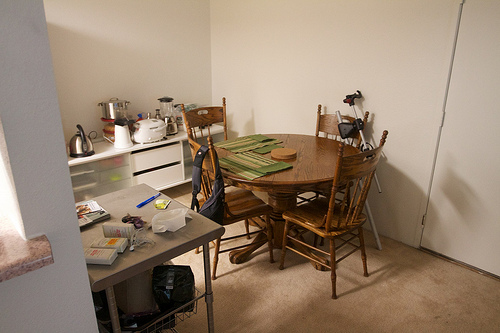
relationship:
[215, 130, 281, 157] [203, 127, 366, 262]
placemat on table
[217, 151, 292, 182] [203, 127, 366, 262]
books on table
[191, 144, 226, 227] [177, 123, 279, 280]
bag on chair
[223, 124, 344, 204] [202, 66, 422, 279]
books on table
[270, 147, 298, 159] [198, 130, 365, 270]
table decoration on table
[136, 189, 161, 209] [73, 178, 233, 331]
blue utencil on table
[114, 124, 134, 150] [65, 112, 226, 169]
box on counter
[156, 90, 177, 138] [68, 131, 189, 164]
metal blender on counter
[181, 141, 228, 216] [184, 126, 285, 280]
bag on chair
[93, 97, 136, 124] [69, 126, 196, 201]
pan on cabinet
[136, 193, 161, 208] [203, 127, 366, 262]
blue utencil on table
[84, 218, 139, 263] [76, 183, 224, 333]
containers on counter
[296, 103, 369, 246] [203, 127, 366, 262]
chair around table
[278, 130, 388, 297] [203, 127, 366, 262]
chair around table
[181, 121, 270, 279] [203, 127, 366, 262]
chair around table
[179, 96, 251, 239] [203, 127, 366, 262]
chair around table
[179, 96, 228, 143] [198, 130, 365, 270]
chair around table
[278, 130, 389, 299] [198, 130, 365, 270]
chair around table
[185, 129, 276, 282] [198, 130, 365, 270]
chair around table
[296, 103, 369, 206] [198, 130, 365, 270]
chair around table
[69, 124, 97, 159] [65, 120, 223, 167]
coffee pot on counter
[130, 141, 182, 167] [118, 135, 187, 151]
drawer on counter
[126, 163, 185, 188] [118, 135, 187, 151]
drawer on counter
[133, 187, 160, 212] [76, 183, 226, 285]
pen on table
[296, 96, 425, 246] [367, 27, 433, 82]
shadow on wall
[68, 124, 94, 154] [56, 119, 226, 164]
coffee pot on counter